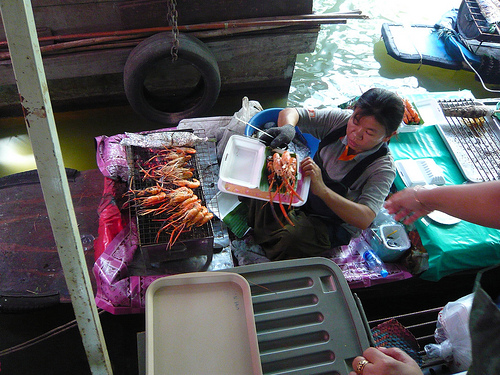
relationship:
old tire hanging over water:
[123, 30, 219, 125] [318, 60, 356, 97]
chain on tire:
[163, 10, 181, 66] [126, 38, 151, 67]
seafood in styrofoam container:
[254, 150, 303, 231] [215, 126, 318, 208]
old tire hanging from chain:
[123, 30, 219, 125] [166, 8, 184, 62]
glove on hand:
[260, 122, 299, 154] [260, 120, 305, 152]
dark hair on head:
[353, 85, 415, 117] [321, 73, 412, 155]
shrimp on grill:
[134, 140, 216, 238] [122, 131, 229, 271]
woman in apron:
[237, 88, 404, 261] [248, 120, 386, 261]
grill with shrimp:
[122, 125, 225, 277] [120, 141, 215, 251]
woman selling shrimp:
[246, 79, 415, 269] [133, 142, 220, 245]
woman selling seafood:
[237, 88, 404, 261] [257, 139, 320, 213]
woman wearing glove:
[237, 88, 404, 261] [255, 124, 307, 151]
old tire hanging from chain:
[123, 30, 219, 125] [167, 1, 181, 67]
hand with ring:
[346, 342, 426, 374] [355, 358, 367, 372]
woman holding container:
[237, 88, 404, 261] [215, 130, 312, 207]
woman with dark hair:
[237, 88, 404, 261] [353, 88, 406, 146]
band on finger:
[357, 360, 370, 375] [347, 349, 380, 371]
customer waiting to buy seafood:
[351, 160, 496, 372] [113, 124, 235, 289]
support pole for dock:
[2, 0, 111, 375] [28, 87, 469, 370]